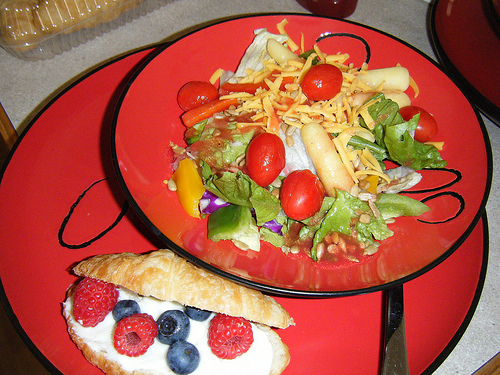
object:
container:
[2, 2, 184, 62]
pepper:
[372, 190, 434, 223]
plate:
[100, 10, 495, 297]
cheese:
[304, 101, 378, 130]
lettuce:
[368, 96, 446, 173]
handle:
[377, 289, 407, 368]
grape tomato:
[279, 168, 326, 220]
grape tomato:
[301, 61, 345, 101]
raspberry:
[72, 275, 117, 327]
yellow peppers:
[170, 156, 207, 220]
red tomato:
[174, 79, 220, 112]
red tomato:
[394, 104, 439, 143]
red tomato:
[244, 130, 287, 187]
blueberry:
[163, 338, 202, 374]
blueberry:
[184, 300, 211, 325]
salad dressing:
[287, 132, 303, 164]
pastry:
[58, 249, 302, 374]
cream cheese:
[248, 339, 280, 373]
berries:
[112, 312, 159, 357]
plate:
[1, 37, 492, 374]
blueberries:
[205, 313, 255, 362]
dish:
[98, 9, 494, 299]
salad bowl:
[119, 7, 494, 287]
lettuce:
[317, 189, 423, 254]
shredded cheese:
[208, 17, 418, 184]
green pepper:
[203, 199, 256, 240]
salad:
[165, 25, 441, 252]